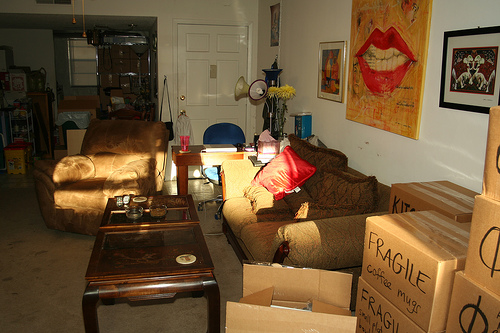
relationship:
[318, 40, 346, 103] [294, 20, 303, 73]
art on wall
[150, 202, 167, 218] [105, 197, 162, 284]
ashtray on top of table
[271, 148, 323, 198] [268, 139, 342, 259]
pillow on couch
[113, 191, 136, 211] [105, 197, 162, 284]
remotes on top of table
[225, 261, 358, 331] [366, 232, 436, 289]
box marked fragile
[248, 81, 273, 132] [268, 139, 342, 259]
lamp by couch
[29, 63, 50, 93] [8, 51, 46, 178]
vase on pile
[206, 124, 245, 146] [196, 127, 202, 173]
chair for desk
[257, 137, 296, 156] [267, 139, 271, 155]
tissues in box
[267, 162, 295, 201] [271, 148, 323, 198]
sunlight on pillow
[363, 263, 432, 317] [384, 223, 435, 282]
coffee mugs in box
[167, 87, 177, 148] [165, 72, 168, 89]
purse on hook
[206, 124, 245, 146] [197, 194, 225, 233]
chair has wheels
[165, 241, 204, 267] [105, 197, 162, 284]
coaster on table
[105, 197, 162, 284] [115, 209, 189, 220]
table has glass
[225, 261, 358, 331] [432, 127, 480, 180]
box near wall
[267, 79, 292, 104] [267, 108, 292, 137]
flowers in vase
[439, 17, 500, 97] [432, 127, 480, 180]
art on wall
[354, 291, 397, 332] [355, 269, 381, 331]
fragile on box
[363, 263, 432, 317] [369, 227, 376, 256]
words in black